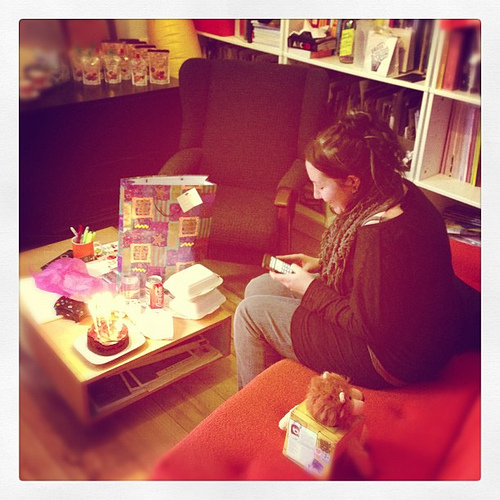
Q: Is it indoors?
A: Yes, it is indoors.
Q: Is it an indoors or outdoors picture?
A: It is indoors.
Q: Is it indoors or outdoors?
A: It is indoors.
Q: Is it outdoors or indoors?
A: It is indoors.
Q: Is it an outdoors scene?
A: No, it is indoors.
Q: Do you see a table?
A: Yes, there is a table.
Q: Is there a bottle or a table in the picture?
A: Yes, there is a table.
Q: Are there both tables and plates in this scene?
A: Yes, there are both a table and a plate.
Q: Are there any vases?
A: No, there are no vases.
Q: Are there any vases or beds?
A: No, there are no vases or beds.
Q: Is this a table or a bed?
A: This is a table.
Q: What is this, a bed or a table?
A: This is a table.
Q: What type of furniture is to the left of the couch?
A: The piece of furniture is a table.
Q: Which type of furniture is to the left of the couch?
A: The piece of furniture is a table.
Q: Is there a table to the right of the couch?
A: No, the table is to the left of the couch.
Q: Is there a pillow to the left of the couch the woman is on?
A: No, there is a table to the left of the couch.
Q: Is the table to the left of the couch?
A: Yes, the table is to the left of the couch.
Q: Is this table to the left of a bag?
A: No, the table is to the left of the couch.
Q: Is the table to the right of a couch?
A: No, the table is to the left of a couch.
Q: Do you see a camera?
A: No, there are no cameras.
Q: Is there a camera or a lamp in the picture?
A: No, there are no cameras or lamps.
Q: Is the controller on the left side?
A: Yes, the controller is on the left of the image.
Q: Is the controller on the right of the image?
A: No, the controller is on the left of the image.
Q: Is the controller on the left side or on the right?
A: The controller is on the left of the image.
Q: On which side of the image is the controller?
A: The controller is on the left of the image.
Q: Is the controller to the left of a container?
A: Yes, the controller is to the left of a container.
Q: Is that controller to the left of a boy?
A: No, the controller is to the left of a container.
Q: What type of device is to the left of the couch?
A: The device is a controller.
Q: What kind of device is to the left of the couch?
A: The device is a controller.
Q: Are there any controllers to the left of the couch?
A: Yes, there is a controller to the left of the couch.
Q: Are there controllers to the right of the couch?
A: No, the controller is to the left of the couch.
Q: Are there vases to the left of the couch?
A: No, there is a controller to the left of the couch.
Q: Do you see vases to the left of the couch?
A: No, there is a controller to the left of the couch.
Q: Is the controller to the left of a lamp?
A: No, the controller is to the left of the couch.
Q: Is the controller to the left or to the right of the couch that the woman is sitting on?
A: The controller is to the left of the couch.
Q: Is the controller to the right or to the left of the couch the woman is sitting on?
A: The controller is to the left of the couch.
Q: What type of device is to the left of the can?
A: The device is a controller.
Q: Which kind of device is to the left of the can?
A: The device is a controller.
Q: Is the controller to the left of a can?
A: Yes, the controller is to the left of a can.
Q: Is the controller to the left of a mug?
A: No, the controller is to the left of a can.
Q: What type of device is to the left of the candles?
A: The device is a controller.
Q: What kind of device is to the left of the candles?
A: The device is a controller.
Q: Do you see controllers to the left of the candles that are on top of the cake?
A: Yes, there is a controller to the left of the candles.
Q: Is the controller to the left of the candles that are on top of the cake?
A: Yes, the controller is to the left of the candles.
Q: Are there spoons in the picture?
A: No, there are no spoons.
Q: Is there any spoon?
A: No, there are no spoons.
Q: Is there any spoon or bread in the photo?
A: No, there are no spoons or breads.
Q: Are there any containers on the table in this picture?
A: Yes, there is a container on the table.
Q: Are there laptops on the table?
A: No, there is a container on the table.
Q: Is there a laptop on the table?
A: No, there is a container on the table.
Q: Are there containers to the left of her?
A: Yes, there is a container to the left of the woman.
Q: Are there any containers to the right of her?
A: No, the container is to the left of the woman.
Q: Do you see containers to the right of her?
A: No, the container is to the left of the woman.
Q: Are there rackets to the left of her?
A: No, there is a container to the left of the woman.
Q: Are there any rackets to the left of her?
A: No, there is a container to the left of the woman.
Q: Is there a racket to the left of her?
A: No, there is a container to the left of the woman.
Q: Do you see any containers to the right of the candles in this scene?
A: Yes, there is a container to the right of the candles.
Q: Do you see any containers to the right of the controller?
A: Yes, there is a container to the right of the controller.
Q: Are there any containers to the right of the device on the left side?
A: Yes, there is a container to the right of the controller.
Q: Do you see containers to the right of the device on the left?
A: Yes, there is a container to the right of the controller.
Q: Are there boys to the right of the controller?
A: No, there is a container to the right of the controller.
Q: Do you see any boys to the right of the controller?
A: No, there is a container to the right of the controller.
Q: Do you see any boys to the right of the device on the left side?
A: No, there is a container to the right of the controller.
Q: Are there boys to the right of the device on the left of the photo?
A: No, there is a container to the right of the controller.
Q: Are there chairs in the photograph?
A: Yes, there is a chair.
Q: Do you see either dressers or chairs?
A: Yes, there is a chair.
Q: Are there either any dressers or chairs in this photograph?
A: Yes, there is a chair.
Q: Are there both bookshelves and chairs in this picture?
A: Yes, there are both a chair and a bookshelf.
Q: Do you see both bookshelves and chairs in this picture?
A: Yes, there are both a chair and a bookshelf.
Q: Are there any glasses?
A: No, there are no glasses.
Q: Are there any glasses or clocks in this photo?
A: No, there are no glasses or clocks.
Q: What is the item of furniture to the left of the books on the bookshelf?
A: The piece of furniture is a chair.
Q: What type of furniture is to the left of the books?
A: The piece of furniture is a chair.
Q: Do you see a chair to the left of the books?
A: Yes, there is a chair to the left of the books.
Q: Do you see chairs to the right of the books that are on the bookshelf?
A: No, the chair is to the left of the books.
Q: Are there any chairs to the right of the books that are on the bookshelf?
A: No, the chair is to the left of the books.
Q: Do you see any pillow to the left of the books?
A: No, there is a chair to the left of the books.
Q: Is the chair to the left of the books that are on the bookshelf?
A: Yes, the chair is to the left of the books.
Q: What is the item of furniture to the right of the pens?
A: The piece of furniture is a chair.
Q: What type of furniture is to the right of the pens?
A: The piece of furniture is a chair.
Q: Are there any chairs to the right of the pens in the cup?
A: Yes, there is a chair to the right of the pens.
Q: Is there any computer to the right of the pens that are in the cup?
A: No, there is a chair to the right of the pens.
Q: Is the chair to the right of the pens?
A: Yes, the chair is to the right of the pens.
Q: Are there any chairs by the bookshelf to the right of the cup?
A: Yes, there is a chair by the bookshelf.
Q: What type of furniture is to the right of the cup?
A: The piece of furniture is a chair.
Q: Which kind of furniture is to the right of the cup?
A: The piece of furniture is a chair.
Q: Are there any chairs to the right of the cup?
A: Yes, there is a chair to the right of the cup.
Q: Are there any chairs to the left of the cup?
A: No, the chair is to the right of the cup.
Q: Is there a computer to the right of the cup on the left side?
A: No, there is a chair to the right of the cup.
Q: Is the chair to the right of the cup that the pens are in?
A: Yes, the chair is to the right of the cup.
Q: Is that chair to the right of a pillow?
A: No, the chair is to the right of the cup.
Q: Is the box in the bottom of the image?
A: Yes, the box is in the bottom of the image.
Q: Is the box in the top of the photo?
A: No, the box is in the bottom of the image.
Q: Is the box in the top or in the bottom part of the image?
A: The box is in the bottom of the image.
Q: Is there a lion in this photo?
A: Yes, there is a lion.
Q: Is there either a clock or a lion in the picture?
A: Yes, there is a lion.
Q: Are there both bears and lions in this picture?
A: No, there is a lion but no bears.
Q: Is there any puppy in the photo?
A: No, there are no puppies.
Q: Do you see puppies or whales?
A: No, there are no puppies or whales.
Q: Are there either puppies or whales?
A: No, there are no puppies or whales.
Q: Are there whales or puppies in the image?
A: No, there are no puppies or whales.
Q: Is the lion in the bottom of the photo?
A: Yes, the lion is in the bottom of the image.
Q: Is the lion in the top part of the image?
A: No, the lion is in the bottom of the image.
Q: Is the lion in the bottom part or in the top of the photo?
A: The lion is in the bottom of the image.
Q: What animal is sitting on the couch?
A: The animal is a lion.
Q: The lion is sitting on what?
A: The lion is sitting on the couch.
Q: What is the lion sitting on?
A: The lion is sitting on the couch.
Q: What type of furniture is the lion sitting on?
A: The lion is sitting on the couch.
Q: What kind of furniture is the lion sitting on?
A: The lion is sitting on the couch.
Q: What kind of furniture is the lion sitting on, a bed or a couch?
A: The lion is sitting on a couch.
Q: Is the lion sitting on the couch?
A: Yes, the lion is sitting on the couch.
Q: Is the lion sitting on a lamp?
A: No, the lion is sitting on the couch.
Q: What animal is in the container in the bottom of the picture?
A: The lion is in the box.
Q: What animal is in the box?
A: The lion is in the box.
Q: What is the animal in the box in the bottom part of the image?
A: The animal is a lion.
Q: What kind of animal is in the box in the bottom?
A: The animal is a lion.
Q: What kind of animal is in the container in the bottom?
A: The animal is a lion.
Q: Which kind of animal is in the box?
A: The animal is a lion.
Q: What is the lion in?
A: The lion is in the box.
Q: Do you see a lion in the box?
A: Yes, there is a lion in the box.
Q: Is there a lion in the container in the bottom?
A: Yes, there is a lion in the box.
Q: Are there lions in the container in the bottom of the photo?
A: Yes, there is a lion in the box.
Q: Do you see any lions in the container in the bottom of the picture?
A: Yes, there is a lion in the box.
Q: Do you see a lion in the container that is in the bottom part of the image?
A: Yes, there is a lion in the box.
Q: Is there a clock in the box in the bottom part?
A: No, there is a lion in the box.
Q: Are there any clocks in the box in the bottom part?
A: No, there is a lion in the box.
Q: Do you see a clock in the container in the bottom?
A: No, there is a lion in the box.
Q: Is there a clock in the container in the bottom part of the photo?
A: No, there is a lion in the box.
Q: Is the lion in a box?
A: Yes, the lion is in a box.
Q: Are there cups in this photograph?
A: Yes, there is a cup.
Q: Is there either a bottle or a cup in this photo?
A: Yes, there is a cup.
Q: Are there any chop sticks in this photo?
A: No, there are no chop sticks.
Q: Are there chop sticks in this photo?
A: No, there are no chop sticks.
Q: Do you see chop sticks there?
A: No, there are no chop sticks.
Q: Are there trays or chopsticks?
A: No, there are no chopsticks or trays.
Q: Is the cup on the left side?
A: Yes, the cup is on the left of the image.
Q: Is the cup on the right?
A: No, the cup is on the left of the image.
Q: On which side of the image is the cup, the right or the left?
A: The cup is on the left of the image.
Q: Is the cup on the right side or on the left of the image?
A: The cup is on the left of the image.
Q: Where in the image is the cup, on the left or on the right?
A: The cup is on the left of the image.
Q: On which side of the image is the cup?
A: The cup is on the left of the image.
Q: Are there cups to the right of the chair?
A: No, the cup is to the left of the chair.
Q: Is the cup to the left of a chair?
A: Yes, the cup is to the left of a chair.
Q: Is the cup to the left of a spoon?
A: No, the cup is to the left of a chair.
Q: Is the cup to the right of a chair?
A: No, the cup is to the left of a chair.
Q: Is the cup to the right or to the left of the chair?
A: The cup is to the left of the chair.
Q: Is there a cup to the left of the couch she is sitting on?
A: Yes, there is a cup to the left of the couch.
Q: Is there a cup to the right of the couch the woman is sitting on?
A: No, the cup is to the left of the couch.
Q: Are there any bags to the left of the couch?
A: No, there is a cup to the left of the couch.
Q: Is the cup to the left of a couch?
A: Yes, the cup is to the left of a couch.